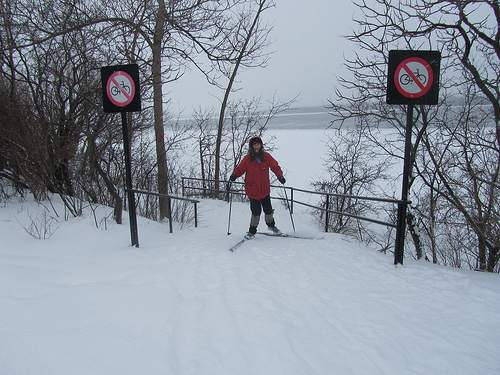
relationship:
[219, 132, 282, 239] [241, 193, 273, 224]
woman wearing pants